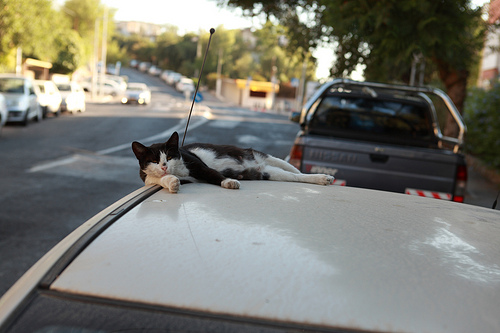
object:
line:
[117, 99, 213, 150]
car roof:
[1, 180, 496, 331]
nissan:
[309, 149, 359, 164]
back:
[292, 135, 469, 200]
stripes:
[404, 185, 454, 202]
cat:
[131, 131, 334, 195]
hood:
[1, 168, 496, 329]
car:
[286, 80, 468, 202]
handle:
[368, 154, 390, 164]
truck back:
[298, 134, 470, 199]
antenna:
[181, 29, 215, 146]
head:
[131, 131, 179, 177]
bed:
[318, 127, 458, 151]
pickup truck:
[288, 82, 468, 204]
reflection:
[425, 212, 499, 284]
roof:
[48, 174, 499, 331]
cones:
[252, 103, 258, 112]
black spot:
[141, 148, 161, 164]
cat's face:
[140, 140, 184, 178]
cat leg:
[262, 167, 335, 185]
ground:
[393, 173, 434, 208]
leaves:
[319, 20, 484, 62]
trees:
[68, 1, 106, 77]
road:
[50, 50, 298, 142]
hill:
[66, 0, 332, 105]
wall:
[285, 102, 357, 178]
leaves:
[43, 26, 53, 40]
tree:
[1, 2, 88, 80]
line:
[26, 144, 126, 173]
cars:
[1, 73, 41, 128]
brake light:
[453, 196, 463, 202]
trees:
[241, 1, 498, 121]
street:
[0, 61, 301, 331]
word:
[308, 149, 358, 164]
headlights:
[121, 98, 128, 103]